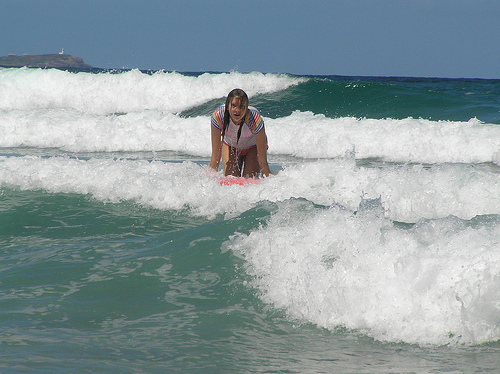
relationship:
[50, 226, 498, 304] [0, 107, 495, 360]
white and green ocean waves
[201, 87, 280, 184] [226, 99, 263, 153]
woman with long blond wet hair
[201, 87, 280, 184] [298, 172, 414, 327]
woman swimming in ocean in waves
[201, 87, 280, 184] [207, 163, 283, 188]
woman on pink board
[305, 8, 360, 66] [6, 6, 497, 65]
white clouds in blue sky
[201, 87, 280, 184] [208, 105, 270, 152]
woman in shirt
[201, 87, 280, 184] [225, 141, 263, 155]
woman in red trunks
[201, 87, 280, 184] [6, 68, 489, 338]
woman bent over in water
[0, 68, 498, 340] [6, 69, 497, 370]
waves in water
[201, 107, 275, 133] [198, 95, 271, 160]
shoulders of shirt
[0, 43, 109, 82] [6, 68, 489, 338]
land mass in water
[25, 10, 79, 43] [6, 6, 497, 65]
white clouds in blue sky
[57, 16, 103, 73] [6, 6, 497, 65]
white clouds in blue sky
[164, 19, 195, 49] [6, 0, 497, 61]
white clouds in blue sky